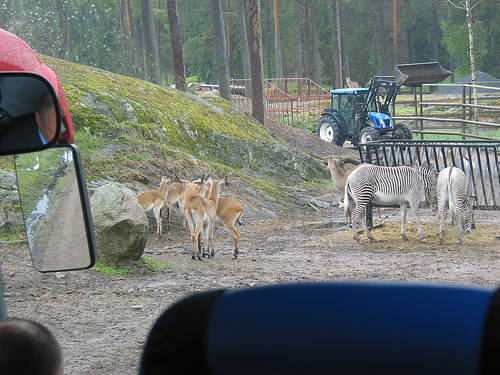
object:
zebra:
[343, 162, 428, 242]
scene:
[1, 1, 499, 374]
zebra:
[433, 165, 473, 246]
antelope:
[179, 175, 225, 262]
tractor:
[315, 60, 457, 153]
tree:
[239, 1, 269, 124]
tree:
[437, 1, 499, 113]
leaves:
[450, 30, 465, 44]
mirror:
[13, 147, 94, 274]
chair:
[135, 279, 498, 374]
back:
[129, 282, 497, 374]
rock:
[85, 178, 149, 258]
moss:
[4, 55, 350, 227]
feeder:
[358, 135, 500, 211]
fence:
[378, 73, 499, 143]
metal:
[226, 73, 331, 124]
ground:
[1, 93, 499, 374]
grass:
[2, 53, 327, 277]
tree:
[166, 0, 190, 90]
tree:
[140, 2, 164, 82]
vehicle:
[1, 19, 99, 374]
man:
[1, 90, 66, 155]